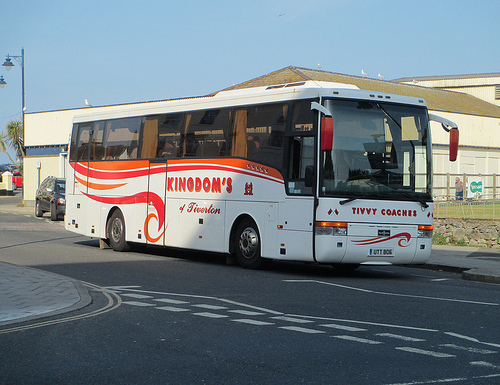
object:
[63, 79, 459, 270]
bus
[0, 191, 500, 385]
road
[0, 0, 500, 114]
sky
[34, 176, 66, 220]
car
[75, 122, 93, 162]
window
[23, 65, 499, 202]
building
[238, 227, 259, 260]
rim